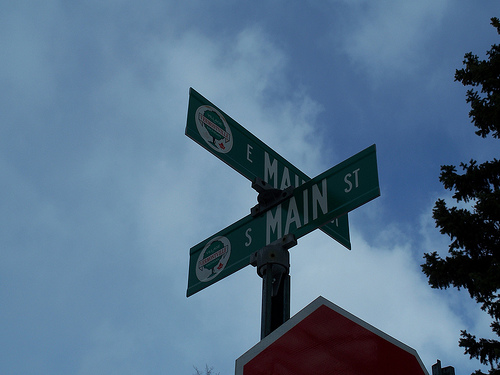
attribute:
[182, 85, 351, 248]
street sign — green, white, rectangular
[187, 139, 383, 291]
street sign — green, rectangular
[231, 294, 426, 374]
stop sign — partial, just the top, the top, red, white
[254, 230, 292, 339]
iron pole — black, metal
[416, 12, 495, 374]
tree — partial, green, leafy, branched, tall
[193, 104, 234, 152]
circular logo — white, green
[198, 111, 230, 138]
letters — red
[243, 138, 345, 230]
e main street — white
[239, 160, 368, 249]
s main st — white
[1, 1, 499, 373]
sky — blue, white, overcast, in background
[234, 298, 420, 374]
border — white